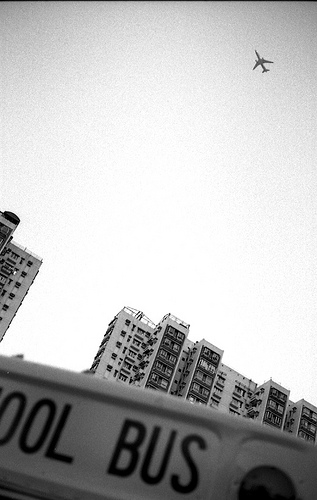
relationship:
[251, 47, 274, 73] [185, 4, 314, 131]
airplane in sky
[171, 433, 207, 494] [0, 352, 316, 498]
letter s are on bus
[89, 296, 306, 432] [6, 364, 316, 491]
building are behind bus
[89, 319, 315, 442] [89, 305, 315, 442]
windows are on buildings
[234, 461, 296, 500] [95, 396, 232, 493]
light on bus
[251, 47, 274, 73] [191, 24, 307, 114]
airplane in sky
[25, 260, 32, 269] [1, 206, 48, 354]
window on building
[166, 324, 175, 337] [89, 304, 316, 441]
window on building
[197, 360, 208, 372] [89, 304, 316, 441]
window on building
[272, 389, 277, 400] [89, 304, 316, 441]
window on building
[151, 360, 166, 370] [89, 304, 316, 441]
window on building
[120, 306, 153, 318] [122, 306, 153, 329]
bars are on roof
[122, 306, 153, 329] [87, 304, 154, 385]
roof on building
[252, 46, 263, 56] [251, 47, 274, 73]
nose on airplane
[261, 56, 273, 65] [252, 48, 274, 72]
wing on plane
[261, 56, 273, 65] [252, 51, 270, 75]
wing on plane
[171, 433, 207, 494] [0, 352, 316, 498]
letter s on bus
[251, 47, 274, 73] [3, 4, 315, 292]
airplane in sky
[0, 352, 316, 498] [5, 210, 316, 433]
bus fronting buildings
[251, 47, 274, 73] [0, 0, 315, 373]
airplane flying in sky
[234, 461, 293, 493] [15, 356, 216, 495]
light on bus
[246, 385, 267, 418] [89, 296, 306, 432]
balconies hanging building